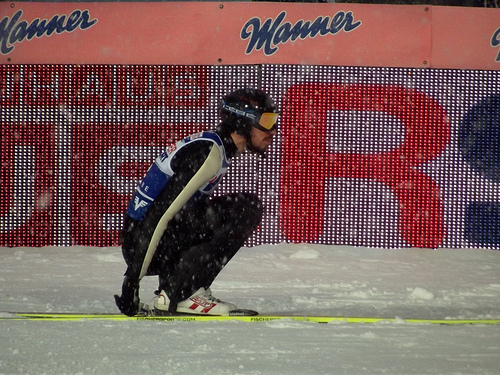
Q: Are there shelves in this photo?
A: No, there are no shelves.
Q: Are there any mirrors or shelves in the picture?
A: No, there are no shelves or mirrors.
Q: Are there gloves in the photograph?
A: Yes, there are gloves.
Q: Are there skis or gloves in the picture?
A: Yes, there are gloves.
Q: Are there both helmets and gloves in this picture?
A: Yes, there are both gloves and a helmet.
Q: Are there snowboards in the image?
A: No, there are no snowboards.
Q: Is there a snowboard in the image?
A: No, there are no snowboards.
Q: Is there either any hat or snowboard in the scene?
A: No, there are no snowboards or hats.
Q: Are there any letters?
A: Yes, there are letters.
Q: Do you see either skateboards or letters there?
A: Yes, there are letters.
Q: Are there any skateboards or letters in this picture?
A: Yes, there are letters.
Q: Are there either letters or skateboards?
A: Yes, there are letters.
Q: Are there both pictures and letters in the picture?
A: No, there are letters but no pictures.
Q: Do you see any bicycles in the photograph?
A: No, there are no bicycles.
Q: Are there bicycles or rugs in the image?
A: No, there are no bicycles or rugs.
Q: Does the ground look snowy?
A: Yes, the ground is snowy.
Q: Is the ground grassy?
A: No, the ground is snowy.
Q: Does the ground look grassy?
A: No, the ground is snowy.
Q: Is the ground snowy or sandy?
A: The ground is snowy.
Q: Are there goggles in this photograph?
A: Yes, there are goggles.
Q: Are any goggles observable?
A: Yes, there are goggles.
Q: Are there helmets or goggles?
A: Yes, there are goggles.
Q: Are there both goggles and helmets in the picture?
A: Yes, there are both goggles and a helmet.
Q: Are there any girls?
A: No, there are no girls.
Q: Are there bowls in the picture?
A: No, there are no bowls.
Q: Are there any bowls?
A: No, there are no bowls.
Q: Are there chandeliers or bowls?
A: No, there are no bowls or chandeliers.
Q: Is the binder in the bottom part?
A: Yes, the binder is in the bottom of the image.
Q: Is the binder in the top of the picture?
A: No, the binder is in the bottom of the image.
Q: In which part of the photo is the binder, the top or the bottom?
A: The binder is in the bottom of the image.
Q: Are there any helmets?
A: Yes, there is a helmet.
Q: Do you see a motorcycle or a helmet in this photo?
A: Yes, there is a helmet.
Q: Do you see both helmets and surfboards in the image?
A: No, there is a helmet but no surfboards.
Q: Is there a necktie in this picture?
A: No, there are no ties.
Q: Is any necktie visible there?
A: No, there are no ties.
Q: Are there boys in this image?
A: No, there are no boys.